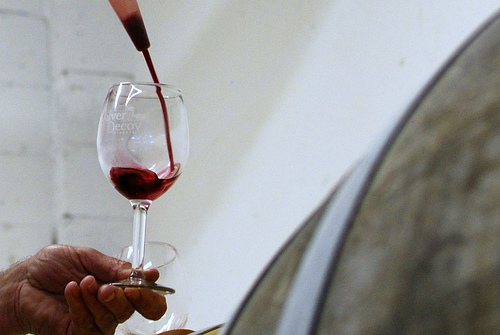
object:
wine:
[130, 69, 198, 144]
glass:
[92, 75, 189, 296]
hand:
[0, 238, 168, 334]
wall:
[214, 8, 288, 67]